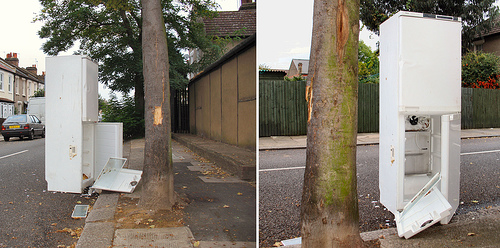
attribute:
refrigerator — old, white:
[40, 49, 148, 222]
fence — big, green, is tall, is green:
[261, 78, 499, 138]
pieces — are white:
[64, 150, 143, 208]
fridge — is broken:
[43, 54, 144, 194]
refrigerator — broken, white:
[20, 49, 151, 220]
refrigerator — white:
[40, 53, 137, 192]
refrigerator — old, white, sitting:
[379, 10, 466, 233]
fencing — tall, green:
[258, 77, 306, 137]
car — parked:
[5, 113, 46, 145]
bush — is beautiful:
[458, 44, 498, 88]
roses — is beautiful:
[487, 75, 497, 85]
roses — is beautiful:
[486, 81, 498, 86]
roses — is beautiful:
[478, 81, 490, 89]